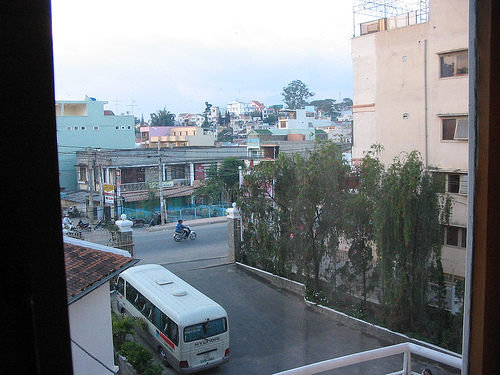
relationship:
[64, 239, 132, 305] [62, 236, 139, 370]
roofing of building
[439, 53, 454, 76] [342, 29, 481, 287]
window on building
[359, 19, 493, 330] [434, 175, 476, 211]
building has a window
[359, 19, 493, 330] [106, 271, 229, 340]
building has windows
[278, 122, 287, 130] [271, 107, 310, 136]
window on building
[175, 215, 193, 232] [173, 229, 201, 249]
person riding a motorbike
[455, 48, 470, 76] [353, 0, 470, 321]
window on a building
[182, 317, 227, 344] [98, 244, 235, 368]
back window of a bus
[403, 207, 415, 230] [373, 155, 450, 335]
leaves on trees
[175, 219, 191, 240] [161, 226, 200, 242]
person wearing a coat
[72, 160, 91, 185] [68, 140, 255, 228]
window on building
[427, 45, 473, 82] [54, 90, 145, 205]
window on building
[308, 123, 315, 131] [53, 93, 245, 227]
window on building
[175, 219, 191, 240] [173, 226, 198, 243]
person riding a motorbike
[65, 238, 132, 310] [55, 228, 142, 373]
roofing on building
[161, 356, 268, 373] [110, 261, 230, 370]
lights of bus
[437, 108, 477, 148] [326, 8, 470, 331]
window on building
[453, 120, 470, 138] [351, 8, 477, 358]
window on a building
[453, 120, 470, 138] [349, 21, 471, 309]
window on a building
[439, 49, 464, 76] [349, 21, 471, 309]
window on a building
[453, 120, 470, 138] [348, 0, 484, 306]
window on a building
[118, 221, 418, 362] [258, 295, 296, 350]
road with tarmac